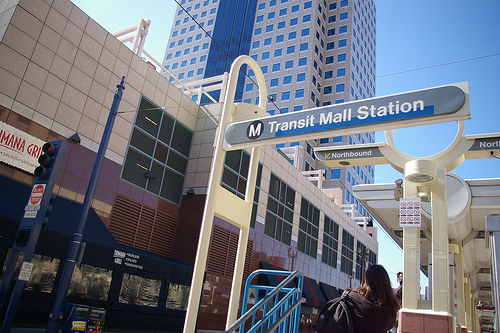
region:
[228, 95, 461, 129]
M transit mall station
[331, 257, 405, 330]
Woman with black backpack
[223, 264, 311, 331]
Bright blue hand rail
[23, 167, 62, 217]
DO NOT ENTER sign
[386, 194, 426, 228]
Small white sign with 'DO-NOTS'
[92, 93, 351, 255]
Building with lots of windows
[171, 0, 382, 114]
Skyscraper with blue windows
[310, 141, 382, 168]
Sign reading Northbound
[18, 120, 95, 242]
Traffic light indicating Stop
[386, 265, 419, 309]
Large woman in the background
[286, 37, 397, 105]
the building is blue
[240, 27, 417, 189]
the building is blue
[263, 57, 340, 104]
the building is blue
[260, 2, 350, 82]
the building is blue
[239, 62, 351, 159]
the building is blue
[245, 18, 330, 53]
the building is blue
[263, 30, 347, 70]
the building is blue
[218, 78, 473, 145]
blue and white train sign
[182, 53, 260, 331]
white metal tube pole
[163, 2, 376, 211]
glass and grey cement sky scraper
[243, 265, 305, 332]
teal blue metal railing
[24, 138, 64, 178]
blue metal stop light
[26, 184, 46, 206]
do not enter sign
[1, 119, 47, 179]
store sign on wall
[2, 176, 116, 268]
blue fabric awning on building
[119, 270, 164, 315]
glass window on wall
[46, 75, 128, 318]
blue metal pole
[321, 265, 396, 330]
a woman carrying a backpack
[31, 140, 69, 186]
a traffic signal light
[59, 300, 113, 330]
2 newspaper boxes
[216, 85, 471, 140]
a subway directional sign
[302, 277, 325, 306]
a blue awning with a red stripe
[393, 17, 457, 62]
a clear, blue sky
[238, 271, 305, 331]
a blue metal hand rail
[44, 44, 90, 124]
part of a tiled building facade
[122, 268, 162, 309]
a clear plastic building window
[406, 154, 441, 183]
a white light fixture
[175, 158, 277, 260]
the post is white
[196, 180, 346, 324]
the post is white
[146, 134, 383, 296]
the post is white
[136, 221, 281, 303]
the post is white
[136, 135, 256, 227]
the post is white